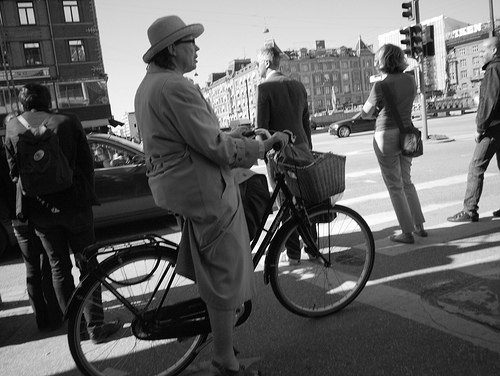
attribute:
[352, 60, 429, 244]
woman — waiting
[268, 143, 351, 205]
basket — brown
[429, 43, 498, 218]
man — waiting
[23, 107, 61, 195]
backpack — black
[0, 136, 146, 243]
car — driving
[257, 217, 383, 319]
tire — black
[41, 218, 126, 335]
pants — dark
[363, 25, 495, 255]
people — waiting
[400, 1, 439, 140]
light — tall